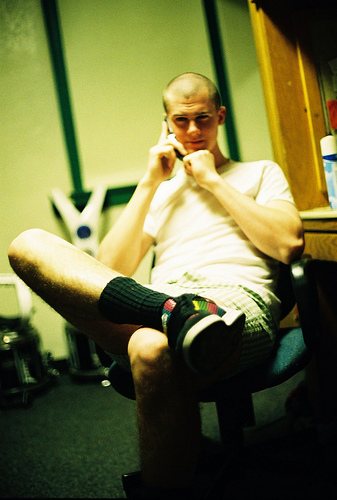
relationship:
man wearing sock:
[5, 68, 305, 500] [95, 269, 184, 334]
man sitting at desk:
[5, 68, 305, 500] [289, 207, 335, 336]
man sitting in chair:
[5, 68, 305, 500] [245, 265, 321, 497]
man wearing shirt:
[5, 68, 305, 500] [140, 157, 295, 312]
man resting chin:
[5, 68, 305, 500] [181, 147, 213, 154]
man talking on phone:
[5, 68, 305, 500] [158, 132, 186, 162]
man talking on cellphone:
[5, 68, 305, 500] [162, 115, 185, 163]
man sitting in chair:
[5, 68, 305, 500] [107, 252, 322, 497]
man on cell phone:
[88, 73, 334, 345] [161, 115, 184, 159]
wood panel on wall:
[249, 0, 323, 215] [246, 0, 329, 212]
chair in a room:
[102, 226, 326, 494] [18, 14, 325, 485]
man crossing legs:
[5, 68, 305, 500] [7, 226, 245, 490]